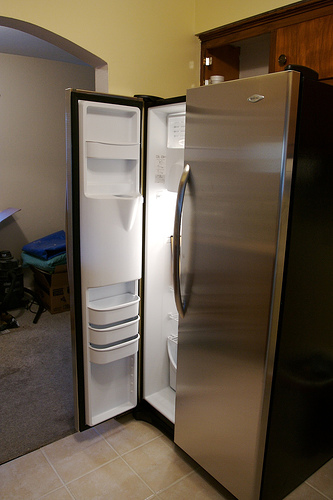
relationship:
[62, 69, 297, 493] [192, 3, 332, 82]
refrigerator in cupboard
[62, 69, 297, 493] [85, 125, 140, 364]
refrigerator has rack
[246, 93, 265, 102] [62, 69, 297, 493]
logo on refrigerator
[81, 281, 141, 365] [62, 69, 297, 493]
shelves in refrigerator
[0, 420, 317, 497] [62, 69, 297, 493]
linoleum under refrigerator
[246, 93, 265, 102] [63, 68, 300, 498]
logo on fridge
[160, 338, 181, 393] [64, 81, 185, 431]
drawer on freezer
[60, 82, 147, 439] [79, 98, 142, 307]
door has shelves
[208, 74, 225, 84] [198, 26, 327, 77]
cup in cupboard